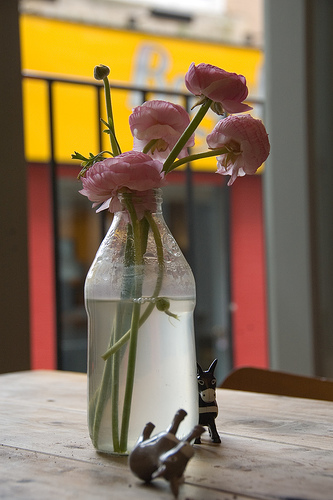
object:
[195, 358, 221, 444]
donkey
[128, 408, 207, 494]
donkey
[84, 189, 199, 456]
bottle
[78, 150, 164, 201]
flower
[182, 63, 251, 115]
flower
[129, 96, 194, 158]
flower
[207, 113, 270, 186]
flower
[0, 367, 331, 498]
table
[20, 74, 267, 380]
railing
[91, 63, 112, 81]
bud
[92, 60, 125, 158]
stem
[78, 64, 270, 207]
flowers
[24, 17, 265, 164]
wall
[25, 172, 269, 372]
wall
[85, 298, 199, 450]
water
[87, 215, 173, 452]
stems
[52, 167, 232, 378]
doors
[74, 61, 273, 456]
arragement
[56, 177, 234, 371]
window